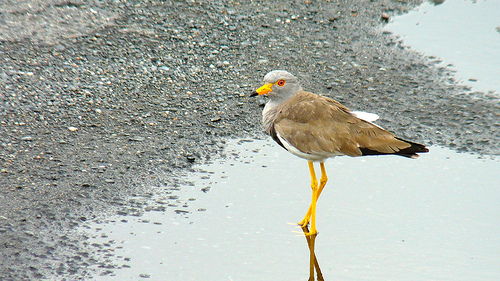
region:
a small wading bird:
[156, 24, 439, 270]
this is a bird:
[170, 31, 456, 251]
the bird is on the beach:
[54, 23, 467, 245]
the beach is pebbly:
[94, 9, 422, 234]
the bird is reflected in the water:
[202, 51, 496, 275]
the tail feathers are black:
[223, 40, 457, 238]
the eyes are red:
[204, 36, 479, 266]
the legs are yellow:
[221, 37, 464, 269]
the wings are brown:
[228, 60, 433, 247]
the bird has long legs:
[214, 36, 451, 251]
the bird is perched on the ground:
[237, 52, 449, 242]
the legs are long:
[284, 143, 373, 255]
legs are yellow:
[285, 147, 331, 244]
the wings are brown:
[272, 100, 397, 167]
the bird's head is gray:
[248, 62, 313, 115]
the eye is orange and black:
[257, 69, 292, 93]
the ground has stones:
[41, 60, 185, 163]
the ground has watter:
[164, 126, 299, 276]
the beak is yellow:
[236, 75, 280, 105]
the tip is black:
[244, 85, 268, 108]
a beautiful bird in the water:
[231, 40, 416, 268]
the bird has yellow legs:
[280, 155, 340, 256]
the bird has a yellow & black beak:
[237, 50, 308, 102]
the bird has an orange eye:
[252, 49, 331, 111]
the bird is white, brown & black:
[241, 43, 466, 240]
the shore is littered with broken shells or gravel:
[78, 47, 230, 144]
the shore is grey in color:
[101, 50, 233, 147]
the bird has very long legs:
[283, 146, 352, 246]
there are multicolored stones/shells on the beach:
[38, 30, 210, 142]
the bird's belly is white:
[256, 112, 360, 170]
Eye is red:
[276, 76, 287, 89]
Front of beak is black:
[247, 88, 259, 99]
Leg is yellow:
[303, 155, 321, 240]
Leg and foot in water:
[300, 156, 322, 242]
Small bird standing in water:
[245, 67, 435, 238]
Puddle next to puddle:
[62, 122, 499, 279]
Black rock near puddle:
[184, 152, 203, 164]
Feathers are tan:
[277, 92, 412, 160]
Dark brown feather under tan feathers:
[356, 122, 431, 161]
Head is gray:
[262, 62, 302, 103]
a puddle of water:
[74, 109, 498, 270]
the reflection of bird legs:
[296, 224, 334, 279]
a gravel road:
[0, 7, 356, 166]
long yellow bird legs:
[300, 151, 338, 234]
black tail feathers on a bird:
[394, 139, 432, 160]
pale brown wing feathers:
[291, 96, 392, 149]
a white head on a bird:
[264, 69, 301, 97]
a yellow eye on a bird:
[276, 75, 286, 86]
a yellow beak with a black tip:
[246, 77, 275, 100]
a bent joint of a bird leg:
[317, 170, 330, 189]